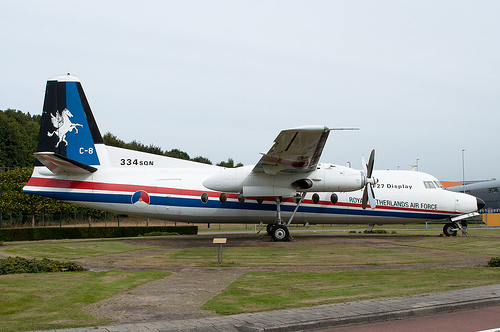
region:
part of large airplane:
[36, 73, 103, 146]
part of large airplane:
[30, 148, 100, 181]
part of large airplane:
[353, 144, 380, 208]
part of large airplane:
[254, 119, 328, 169]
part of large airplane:
[200, 163, 366, 195]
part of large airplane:
[271, 196, 301, 243]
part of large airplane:
[441, 220, 460, 239]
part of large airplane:
[103, 145, 487, 232]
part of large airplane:
[289, 172, 316, 199]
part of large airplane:
[325, 122, 364, 137]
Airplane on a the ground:
[24, 55, 479, 287]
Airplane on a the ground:
[328, 126, 498, 247]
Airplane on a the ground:
[14, 65, 183, 274]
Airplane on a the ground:
[153, 118, 362, 258]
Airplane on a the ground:
[267, 115, 390, 253]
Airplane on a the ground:
[23, 68, 483, 245]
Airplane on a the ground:
[21, 65, 481, 237]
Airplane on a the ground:
[24, 60, 482, 243]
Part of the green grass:
[260, 295, 271, 300]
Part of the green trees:
[6, 124, 20, 154]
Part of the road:
[450, 316, 467, 329]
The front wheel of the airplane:
[441, 219, 460, 237]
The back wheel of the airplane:
[267, 221, 292, 243]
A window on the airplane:
[198, 189, 208, 206]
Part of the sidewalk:
[153, 295, 174, 310]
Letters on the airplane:
[409, 197, 439, 212]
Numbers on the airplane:
[118, 154, 140, 166]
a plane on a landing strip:
[10, 68, 487, 241]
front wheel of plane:
[437, 217, 467, 241]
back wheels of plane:
[257, 217, 292, 242]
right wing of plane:
[252, 120, 332, 175]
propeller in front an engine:
[353, 143, 383, 213]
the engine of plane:
[204, 163, 364, 199]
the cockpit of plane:
[408, 163, 450, 200]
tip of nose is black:
[443, 180, 493, 221]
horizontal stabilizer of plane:
[26, 142, 97, 182]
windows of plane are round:
[194, 183, 345, 208]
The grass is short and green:
[241, 266, 411, 301]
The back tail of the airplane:
[33, 69, 110, 179]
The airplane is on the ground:
[6, 42, 498, 328]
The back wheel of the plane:
[264, 218, 294, 244]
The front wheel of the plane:
[440, 216, 462, 240]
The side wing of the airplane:
[198, 119, 382, 214]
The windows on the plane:
[191, 187, 344, 212]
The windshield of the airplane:
[422, 175, 447, 192]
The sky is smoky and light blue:
[101, 16, 451, 113]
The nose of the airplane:
[447, 183, 488, 224]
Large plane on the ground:
[32, 70, 477, 259]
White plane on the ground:
[17, 74, 484, 249]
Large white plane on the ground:
[24, 64, 487, 257]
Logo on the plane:
[43, 105, 91, 151]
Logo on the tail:
[46, 102, 92, 152]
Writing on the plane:
[331, 170, 442, 212]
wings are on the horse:
[49, 111, 63, 126]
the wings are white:
[45, 110, 65, 125]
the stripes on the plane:
[98, 175, 435, 217]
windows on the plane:
[202, 192, 347, 205]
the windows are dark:
[200, 195, 344, 209]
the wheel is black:
[272, 222, 292, 245]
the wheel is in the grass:
[270, 225, 296, 245]